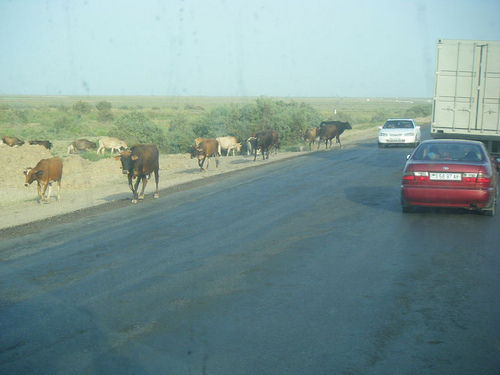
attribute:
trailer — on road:
[428, 37, 498, 141]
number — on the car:
[426, 169, 463, 184]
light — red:
[400, 167, 430, 179]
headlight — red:
[378, 131, 388, 138]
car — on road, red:
[395, 130, 498, 219]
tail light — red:
[400, 170, 430, 182]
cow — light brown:
[22, 157, 62, 205]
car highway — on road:
[373, 117, 419, 147]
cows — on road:
[0, 118, 352, 203]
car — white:
[377, 115, 417, 144]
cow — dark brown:
[120, 139, 163, 201]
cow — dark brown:
[188, 133, 222, 172]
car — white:
[378, 114, 427, 160]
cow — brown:
[117, 142, 159, 203]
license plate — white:
[429, 171, 462, 181]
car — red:
[401, 139, 498, 213]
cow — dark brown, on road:
[21, 155, 66, 202]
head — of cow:
[114, 147, 141, 185]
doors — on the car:
[436, 35, 493, 129]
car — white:
[364, 112, 418, 152]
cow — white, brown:
[19, 153, 83, 205]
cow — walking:
[296, 120, 380, 171]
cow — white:
[95, 136, 128, 159]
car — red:
[397, 138, 483, 212]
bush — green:
[110, 111, 157, 139]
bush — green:
[159, 130, 195, 153]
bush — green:
[187, 115, 215, 135]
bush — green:
[166, 111, 193, 134]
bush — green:
[94, 107, 113, 120]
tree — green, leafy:
[253, 98, 277, 125]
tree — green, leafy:
[92, 105, 114, 121]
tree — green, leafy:
[91, 99, 115, 113]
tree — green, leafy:
[69, 97, 93, 116]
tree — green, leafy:
[164, 111, 190, 132]